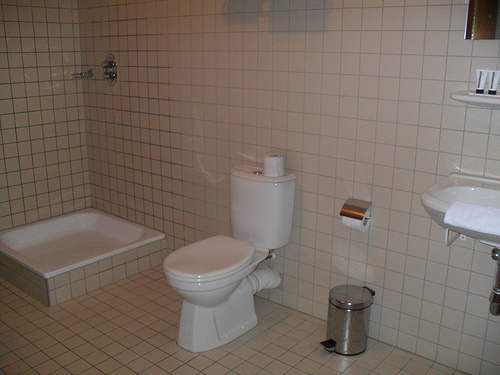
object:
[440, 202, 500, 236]
towel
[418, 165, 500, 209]
sink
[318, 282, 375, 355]
trash can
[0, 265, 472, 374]
floor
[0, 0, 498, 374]
bathroom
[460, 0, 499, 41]
mirror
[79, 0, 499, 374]
wall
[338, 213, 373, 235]
toilet paper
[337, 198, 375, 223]
toilet roll holder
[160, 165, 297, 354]
toilet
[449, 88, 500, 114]
shelf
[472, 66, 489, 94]
bottle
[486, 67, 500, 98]
bottle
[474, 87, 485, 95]
cap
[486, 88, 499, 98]
cap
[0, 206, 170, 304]
shower base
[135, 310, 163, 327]
tiles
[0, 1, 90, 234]
wall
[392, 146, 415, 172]
tile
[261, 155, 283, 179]
toilet paper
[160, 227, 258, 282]
lid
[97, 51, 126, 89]
shower mechanism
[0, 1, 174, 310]
shower stall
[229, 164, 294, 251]
tank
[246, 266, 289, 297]
pipe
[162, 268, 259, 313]
bowl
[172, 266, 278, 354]
base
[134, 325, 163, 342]
tile